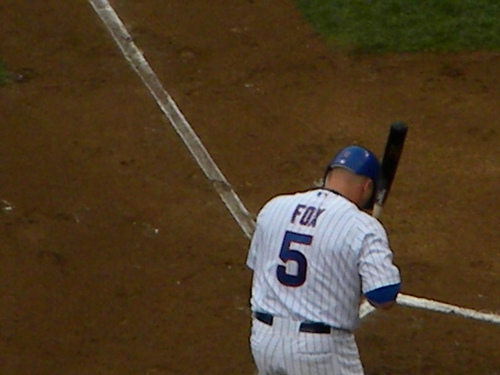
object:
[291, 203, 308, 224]
letter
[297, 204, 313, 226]
letter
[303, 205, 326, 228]
letter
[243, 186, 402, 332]
jersey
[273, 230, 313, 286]
5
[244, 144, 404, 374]
batter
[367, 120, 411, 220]
bat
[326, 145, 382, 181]
helmet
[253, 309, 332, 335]
belt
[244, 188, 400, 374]
uniform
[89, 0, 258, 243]
line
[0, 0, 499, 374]
dirt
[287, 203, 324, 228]
fox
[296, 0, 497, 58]
grass patch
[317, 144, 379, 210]
head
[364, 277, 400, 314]
elbow